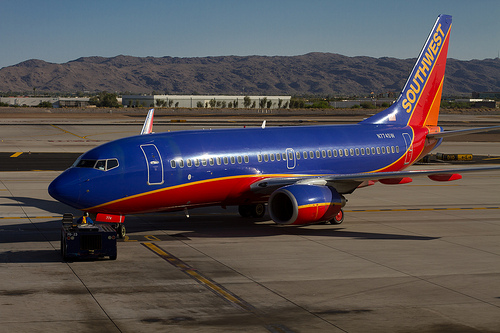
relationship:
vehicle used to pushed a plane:
[60, 212, 117, 261] [45, 13, 498, 238]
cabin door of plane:
[139, 142, 166, 185] [45, 13, 498, 238]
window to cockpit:
[105, 154, 119, 169] [71, 140, 124, 177]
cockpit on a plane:
[71, 140, 124, 177] [45, 13, 498, 238]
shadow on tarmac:
[3, 193, 443, 263] [2, 116, 499, 330]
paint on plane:
[45, 116, 439, 241] [44, 10, 465, 256]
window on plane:
[91, 156, 121, 173] [45, 13, 498, 238]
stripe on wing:
[161, 124, 498, 245] [262, 151, 486, 215]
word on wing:
[401, 20, 444, 112] [317, 166, 498, 170]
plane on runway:
[45, 13, 498, 238] [6, 117, 496, 329]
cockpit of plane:
[75, 151, 125, 180] [45, 13, 498, 238]